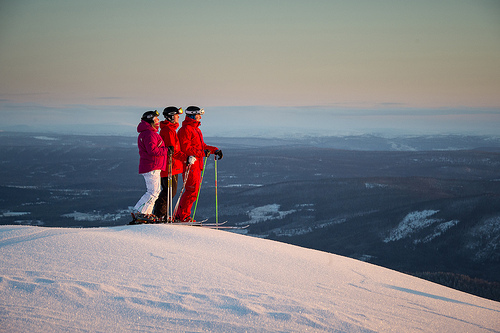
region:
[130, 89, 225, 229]
three skiers standing on a mountain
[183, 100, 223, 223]
skier wearing all red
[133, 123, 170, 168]
pink coat of woman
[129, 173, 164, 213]
white pants of woman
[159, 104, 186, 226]
person wearing red coat and black pants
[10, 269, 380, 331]
tracks in the snow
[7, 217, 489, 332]
mountain skiers are standing on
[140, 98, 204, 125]
black helmets of skiers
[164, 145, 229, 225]
ski poles of skiers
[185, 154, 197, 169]
white glove of skier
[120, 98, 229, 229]
three skiers standing together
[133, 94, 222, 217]
skiers looking off into the distance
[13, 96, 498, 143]
low hanging clouds over mountains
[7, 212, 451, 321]
shadows on the white snow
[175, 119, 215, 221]
skier wearing red pants and coat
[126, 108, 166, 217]
skier wearing white pants and pink coat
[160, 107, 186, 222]
skier wearing red coat and black pants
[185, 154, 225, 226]
green ski poles of person in all red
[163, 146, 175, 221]
ski poles of woman wearing pink coat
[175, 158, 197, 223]
ski poles of man in the middle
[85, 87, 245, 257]
three people in the snow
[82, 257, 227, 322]
footprints in the snow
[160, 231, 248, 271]
white snow on ground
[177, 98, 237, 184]
person wearing the color red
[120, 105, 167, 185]
lady wearing the color pink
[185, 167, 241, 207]
ski poles on the ground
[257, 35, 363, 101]
sky in the background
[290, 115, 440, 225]
land in the distance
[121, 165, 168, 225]
white pants on person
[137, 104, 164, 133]
head of a person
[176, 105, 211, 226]
A person in a sketing suit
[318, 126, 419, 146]
A cloudy mountain horizon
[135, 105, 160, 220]
A person in a sketing suit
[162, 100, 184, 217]
A person in a sketing suit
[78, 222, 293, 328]
A heap of snow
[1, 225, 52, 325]
A heap of snow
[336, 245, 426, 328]
A heap of snow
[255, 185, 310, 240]
A valley covered with snow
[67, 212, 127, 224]
A valley covered with snow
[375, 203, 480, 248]
A valley covered with snow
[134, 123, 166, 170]
The pink coat the lady is wearing.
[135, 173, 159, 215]
The white pants the lady is wearing.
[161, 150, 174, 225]
The ski poles in the lady's hand in the pink coat.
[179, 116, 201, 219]
The red snow suit the man is wearing.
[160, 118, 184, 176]
The red coat the person in the middle is wearing.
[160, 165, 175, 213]
The black pants the person in the middle is wearing.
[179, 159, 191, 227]
The ski poles the person in the red coat is wearing.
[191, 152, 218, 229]
The ski poles the person in the red snow suit is wearing.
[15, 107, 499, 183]
The mountains in the distance.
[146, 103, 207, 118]
The snow goggles on the skiers heads.